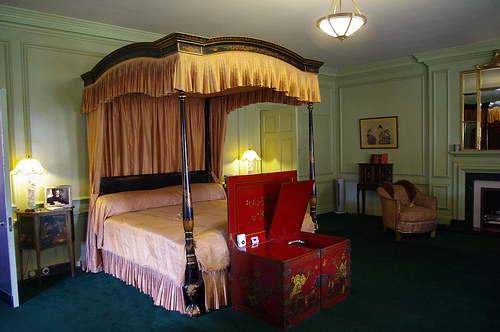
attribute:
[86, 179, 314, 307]
bed — pink, canopied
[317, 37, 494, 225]
wall — green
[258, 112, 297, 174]
door — open, green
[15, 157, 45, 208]
lamp — on, small, white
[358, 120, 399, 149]
painting — framed, oriental, brown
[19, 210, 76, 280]
table — small, wooden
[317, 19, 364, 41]
light — on, gold, white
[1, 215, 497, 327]
carpet — blue, teal blue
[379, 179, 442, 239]
chair — pink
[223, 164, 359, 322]
chest — red, ornate, decorated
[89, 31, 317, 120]
canopy — gold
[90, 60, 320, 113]
ruffle — pink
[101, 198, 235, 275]
bedspread — pink, ruffled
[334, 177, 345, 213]
heater — cylindrical, white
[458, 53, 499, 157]
mirror — ornate, gold, gilded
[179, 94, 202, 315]
posts — black, gold